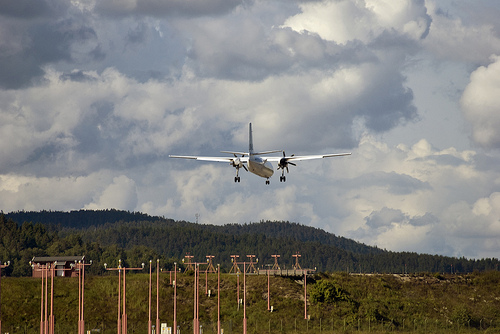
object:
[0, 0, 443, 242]
dark clouds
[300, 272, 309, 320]
power lines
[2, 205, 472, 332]
mountainous terrain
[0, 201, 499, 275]
green mountains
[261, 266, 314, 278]
small bridge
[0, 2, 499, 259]
air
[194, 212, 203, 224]
tower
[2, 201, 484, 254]
distance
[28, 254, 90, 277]
building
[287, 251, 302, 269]
red structures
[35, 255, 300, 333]
lines-of-lights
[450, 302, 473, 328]
trees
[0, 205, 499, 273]
forest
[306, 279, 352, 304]
bush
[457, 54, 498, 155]
clouds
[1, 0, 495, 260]
sky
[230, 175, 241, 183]
landing gear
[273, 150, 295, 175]
propeller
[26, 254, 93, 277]
house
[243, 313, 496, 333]
fencing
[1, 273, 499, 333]
ground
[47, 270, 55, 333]
posts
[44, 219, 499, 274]
mountains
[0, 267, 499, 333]
hills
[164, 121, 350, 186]
plane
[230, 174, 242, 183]
wheels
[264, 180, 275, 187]
wheels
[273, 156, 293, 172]
plane's engine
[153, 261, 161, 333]
lighting system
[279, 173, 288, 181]
landing gear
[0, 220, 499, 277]
hill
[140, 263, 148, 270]
approach lights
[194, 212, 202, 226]
communication tower